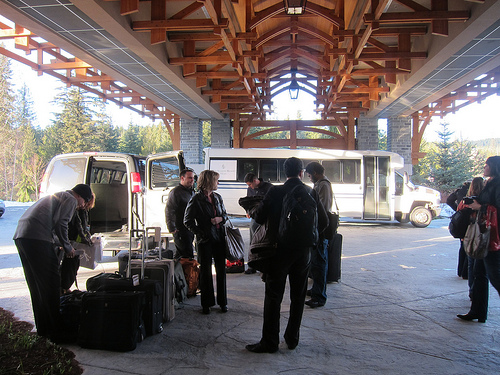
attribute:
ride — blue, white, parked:
[202, 147, 443, 227]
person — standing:
[182, 170, 246, 315]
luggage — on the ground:
[60, 290, 141, 352]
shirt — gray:
[12, 190, 77, 254]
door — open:
[144, 150, 184, 250]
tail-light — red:
[129, 172, 144, 195]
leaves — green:
[432, 154, 470, 180]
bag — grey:
[462, 207, 493, 261]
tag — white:
[131, 272, 140, 289]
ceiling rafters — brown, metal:
[174, 3, 416, 72]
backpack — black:
[278, 183, 320, 250]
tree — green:
[428, 121, 474, 198]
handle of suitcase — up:
[127, 229, 147, 282]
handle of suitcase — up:
[144, 225, 163, 259]